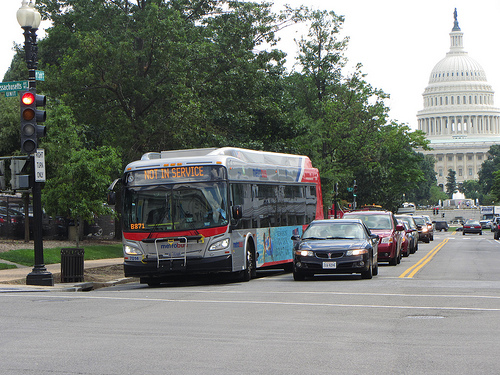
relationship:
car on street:
[287, 209, 381, 284] [224, 301, 342, 375]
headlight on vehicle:
[294, 245, 367, 261] [287, 209, 381, 284]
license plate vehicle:
[318, 261, 340, 270] [287, 209, 381, 284]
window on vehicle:
[303, 221, 366, 243] [287, 209, 381, 284]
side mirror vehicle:
[372, 233, 383, 243] [287, 209, 381, 284]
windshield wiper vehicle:
[303, 221, 366, 243] [287, 209, 381, 284]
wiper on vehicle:
[300, 234, 358, 242] [287, 209, 381, 284]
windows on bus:
[226, 175, 319, 227] [114, 145, 326, 286]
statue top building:
[449, 8, 462, 34] [415, 9, 498, 203]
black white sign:
[34, 151, 52, 183] [34, 149, 52, 181]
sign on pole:
[34, 149, 52, 181] [19, 6, 53, 285]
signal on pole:
[16, 90, 42, 154] [19, 6, 53, 285]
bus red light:
[114, 145, 326, 286] [18, 92, 38, 108]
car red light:
[287, 209, 381, 284] [18, 92, 38, 108]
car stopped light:
[287, 209, 381, 284] [18, 92, 38, 108]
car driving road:
[287, 209, 381, 284] [217, 304, 401, 367]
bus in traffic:
[114, 145, 326, 286] [293, 202, 499, 290]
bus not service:
[114, 145, 326, 286] [170, 167, 203, 179]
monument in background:
[415, 9, 498, 203] [370, 5, 423, 81]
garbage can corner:
[56, 245, 92, 285] [59, 282, 95, 299]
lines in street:
[393, 234, 464, 285] [224, 301, 342, 375]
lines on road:
[393, 234, 464, 285] [217, 304, 401, 367]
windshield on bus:
[119, 167, 237, 235] [114, 145, 326, 286]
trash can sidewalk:
[56, 245, 92, 285] [51, 252, 123, 268]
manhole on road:
[393, 306, 450, 327] [217, 304, 401, 367]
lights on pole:
[22, 94, 52, 155] [19, 6, 53, 285]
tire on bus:
[240, 240, 260, 281] [114, 145, 326, 286]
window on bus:
[121, 174, 315, 227] [114, 145, 326, 286]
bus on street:
[114, 145, 326, 286] [224, 301, 342, 375]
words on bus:
[132, 167, 219, 181] [114, 145, 326, 286]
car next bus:
[287, 209, 381, 284] [114, 145, 326, 286]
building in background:
[415, 9, 498, 203] [370, 5, 423, 81]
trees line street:
[293, 80, 432, 200] [224, 301, 342, 375]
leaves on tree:
[74, 18, 261, 133] [39, 4, 211, 243]